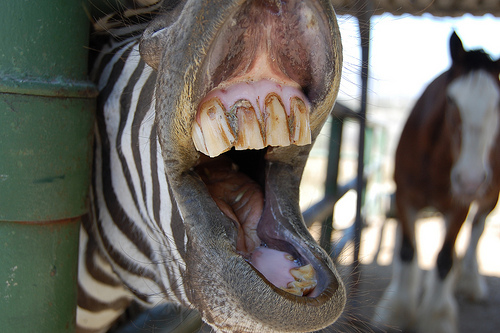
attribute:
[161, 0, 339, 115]
lip — top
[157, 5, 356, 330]
mouth — pink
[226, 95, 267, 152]
tooth — rotten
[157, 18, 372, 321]
mouth — open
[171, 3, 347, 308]
mouth — open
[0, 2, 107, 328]
bar — metal, green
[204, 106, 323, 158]
teeth — gross, yellow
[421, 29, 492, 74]
ear — brown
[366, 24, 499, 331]
horse — clydesdale, white, brown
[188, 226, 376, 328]
lip — bottom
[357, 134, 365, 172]
bar — metal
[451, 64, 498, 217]
face — brown, white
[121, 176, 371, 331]
fence — metal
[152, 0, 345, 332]
lips — speckled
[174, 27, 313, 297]
mouth — open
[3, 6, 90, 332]
building — green, white